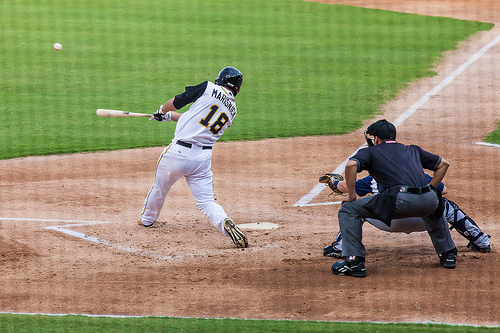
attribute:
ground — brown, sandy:
[225, 255, 495, 329]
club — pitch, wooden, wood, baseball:
[98, 107, 163, 119]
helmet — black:
[213, 64, 246, 96]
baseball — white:
[53, 43, 64, 52]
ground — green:
[0, 1, 496, 160]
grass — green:
[2, 320, 495, 331]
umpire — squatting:
[334, 119, 460, 278]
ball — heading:
[56, 41, 62, 50]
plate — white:
[235, 220, 280, 231]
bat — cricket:
[98, 110, 170, 122]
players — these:
[136, 68, 499, 278]